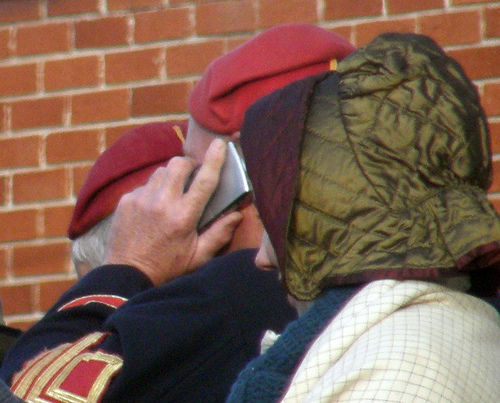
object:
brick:
[12, 21, 73, 54]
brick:
[11, 95, 63, 128]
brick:
[106, 48, 158, 83]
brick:
[10, 169, 68, 205]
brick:
[193, 1, 253, 35]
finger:
[160, 155, 200, 194]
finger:
[183, 138, 226, 228]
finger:
[188, 211, 242, 269]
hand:
[101, 139, 242, 287]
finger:
[146, 166, 166, 191]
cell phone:
[183, 140, 255, 232]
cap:
[189, 23, 356, 133]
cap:
[66, 117, 187, 241]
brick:
[69, 87, 132, 128]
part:
[71, 96, 88, 120]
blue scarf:
[227, 284, 350, 401]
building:
[0, 1, 499, 331]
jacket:
[262, 281, 500, 401]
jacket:
[1, 249, 296, 401]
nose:
[255, 235, 274, 272]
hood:
[242, 36, 499, 299]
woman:
[229, 32, 499, 402]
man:
[4, 26, 353, 402]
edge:
[350, 346, 397, 385]